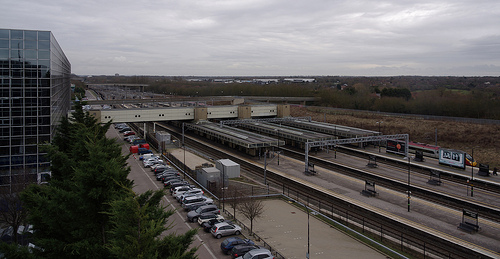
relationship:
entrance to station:
[155, 119, 184, 141] [104, 116, 445, 177]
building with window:
[1, 29, 71, 195] [38, 41, 50, 49]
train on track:
[408, 142, 476, 167] [479, 163, 499, 172]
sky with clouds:
[0, 1, 499, 77] [0, 0, 499, 79]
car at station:
[180, 196, 213, 209] [104, 116, 445, 177]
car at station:
[188, 204, 220, 221] [104, 116, 445, 177]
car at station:
[209, 222, 242, 239] [104, 116, 445, 177]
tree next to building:
[105, 191, 203, 258] [1, 29, 71, 195]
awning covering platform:
[186, 119, 284, 147] [181, 121, 289, 156]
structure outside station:
[304, 132, 409, 172] [104, 116, 445, 177]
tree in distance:
[337, 84, 343, 90] [60, 75, 500, 141]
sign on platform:
[386, 140, 407, 153] [340, 129, 500, 184]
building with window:
[1, 29, 71, 195] [37, 31, 51, 42]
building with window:
[1, 29, 71, 195] [38, 50, 50, 61]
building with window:
[1, 29, 71, 195] [10, 88, 24, 98]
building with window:
[1, 29, 71, 195] [24, 97, 39, 109]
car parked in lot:
[211, 222, 239, 239] [101, 124, 276, 257]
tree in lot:
[241, 186, 261, 240] [101, 124, 276, 257]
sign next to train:
[439, 149, 466, 167] [408, 142, 476, 167]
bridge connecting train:
[87, 103, 288, 125] [408, 141, 477, 166]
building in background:
[266, 79, 281, 85] [69, 76, 498, 117]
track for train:
[479, 163, 499, 172] [408, 142, 476, 167]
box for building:
[197, 168, 220, 186] [171, 147, 216, 168]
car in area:
[188, 204, 220, 221] [101, 124, 276, 257]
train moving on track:
[408, 142, 476, 167] [479, 163, 499, 172]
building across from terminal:
[1, 29, 71, 195] [186, 117, 291, 158]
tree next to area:
[241, 186, 261, 240] [101, 124, 276, 257]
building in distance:
[266, 79, 281, 85] [60, 75, 500, 141]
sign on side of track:
[439, 149, 466, 167] [479, 163, 499, 172]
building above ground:
[87, 103, 288, 125] [70, 76, 499, 258]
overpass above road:
[77, 92, 319, 111] [86, 103, 108, 116]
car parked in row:
[188, 204, 220, 221] [116, 123, 273, 257]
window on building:
[10, 88, 24, 98] [1, 29, 71, 195]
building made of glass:
[1, 29, 71, 195] [25, 117, 39, 126]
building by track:
[171, 147, 216, 168] [155, 121, 489, 255]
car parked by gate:
[209, 222, 242, 239] [158, 141, 163, 157]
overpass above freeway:
[78, 94, 323, 104] [82, 89, 101, 102]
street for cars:
[101, 125, 219, 257] [116, 123, 273, 257]